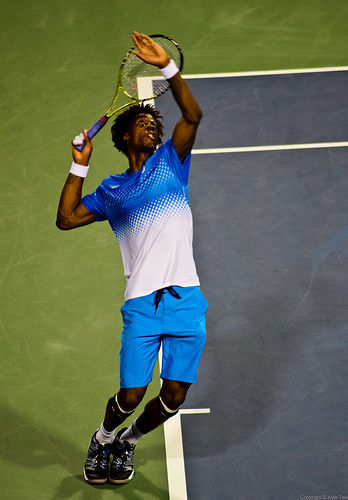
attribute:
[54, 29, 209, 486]
man — playing tennis, black, reaching, serving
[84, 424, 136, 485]
shoes — black blue, white, black, blue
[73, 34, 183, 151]
tennis racket — tennis racket, purple, neon green, black, yellow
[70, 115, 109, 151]
handle — blue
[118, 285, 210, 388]
shorts — blue, bright blue, long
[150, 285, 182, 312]
drawstring — black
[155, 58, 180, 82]
wristband — white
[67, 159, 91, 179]
wristband — white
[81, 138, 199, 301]
shirt — white, blue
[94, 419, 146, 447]
socks — white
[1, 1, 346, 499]
tennis court — grey, green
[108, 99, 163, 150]
hair — dark